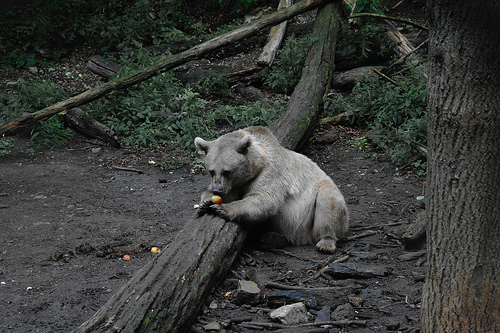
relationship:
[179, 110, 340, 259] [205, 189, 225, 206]
bear eats fruit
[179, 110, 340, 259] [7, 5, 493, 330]
bear on photo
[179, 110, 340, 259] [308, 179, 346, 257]
bear has leg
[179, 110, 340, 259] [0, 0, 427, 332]
bear on ground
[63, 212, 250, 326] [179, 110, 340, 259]
log front bear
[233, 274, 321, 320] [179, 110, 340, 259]
stuff next bear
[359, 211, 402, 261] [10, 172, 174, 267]
part of a ground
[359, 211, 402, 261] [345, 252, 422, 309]
part of a ground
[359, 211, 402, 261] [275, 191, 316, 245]
part of a tummy